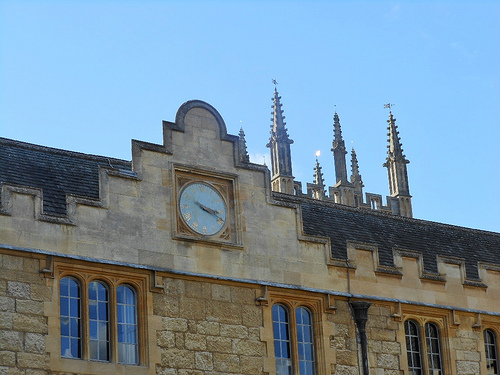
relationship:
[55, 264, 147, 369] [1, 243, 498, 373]
window in wall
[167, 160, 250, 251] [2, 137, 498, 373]
clock in building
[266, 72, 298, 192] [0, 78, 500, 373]
spire on building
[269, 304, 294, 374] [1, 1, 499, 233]
window reflecting sky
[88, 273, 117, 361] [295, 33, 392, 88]
window reflecting sky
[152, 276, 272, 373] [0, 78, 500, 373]
stones on building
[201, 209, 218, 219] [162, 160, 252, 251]
hand on clock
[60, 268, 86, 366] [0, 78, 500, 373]
window on building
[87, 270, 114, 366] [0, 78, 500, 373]
window on building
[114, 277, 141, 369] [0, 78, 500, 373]
window on building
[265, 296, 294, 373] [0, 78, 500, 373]
window on building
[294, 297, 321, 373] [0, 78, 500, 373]
window on building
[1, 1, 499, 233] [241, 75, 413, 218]
sky above building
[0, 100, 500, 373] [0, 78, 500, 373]
bricks on building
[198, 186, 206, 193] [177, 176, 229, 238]
number on clock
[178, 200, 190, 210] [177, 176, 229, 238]
number on clock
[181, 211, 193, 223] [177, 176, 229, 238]
number on clock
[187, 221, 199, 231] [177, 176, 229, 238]
number on clock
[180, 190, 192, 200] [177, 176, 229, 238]
number on clock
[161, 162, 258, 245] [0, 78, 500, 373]
clock on building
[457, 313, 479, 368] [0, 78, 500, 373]
stone to building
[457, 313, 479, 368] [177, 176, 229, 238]
stone to clock